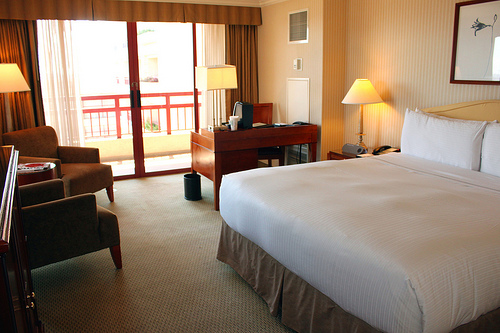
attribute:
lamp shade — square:
[194, 64, 240, 91]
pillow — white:
[401, 107, 487, 172]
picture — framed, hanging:
[449, 0, 499, 86]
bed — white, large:
[217, 99, 498, 331]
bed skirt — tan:
[216, 213, 499, 332]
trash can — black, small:
[183, 173, 201, 202]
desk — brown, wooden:
[190, 121, 317, 210]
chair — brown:
[0, 124, 115, 206]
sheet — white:
[219, 152, 498, 332]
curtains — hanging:
[1, 0, 262, 134]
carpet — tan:
[28, 170, 296, 331]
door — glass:
[72, 21, 201, 179]